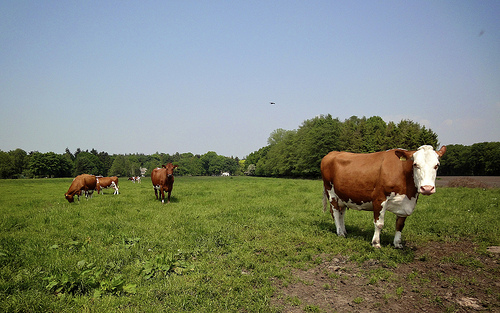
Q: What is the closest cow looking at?
A: The camera.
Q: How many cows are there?
A: Five.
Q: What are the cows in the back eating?
A: Grass.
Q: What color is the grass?
A: Green.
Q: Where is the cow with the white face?
A: Closest to the camera.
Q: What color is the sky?
A: Blue.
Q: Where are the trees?
A: Behind the cows.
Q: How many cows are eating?
A: One.